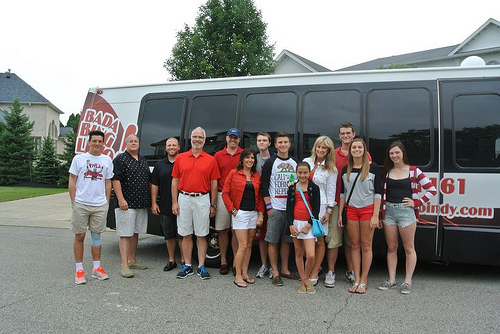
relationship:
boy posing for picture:
[67, 130, 115, 286] [1, 0, 494, 332]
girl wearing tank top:
[377, 139, 436, 294] [380, 167, 418, 202]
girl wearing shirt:
[337, 136, 385, 293] [337, 162, 386, 207]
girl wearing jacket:
[285, 161, 322, 291] [284, 178, 321, 225]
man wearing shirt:
[221, 124, 242, 171] [207, 150, 238, 177]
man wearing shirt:
[171, 126, 221, 280] [169, 144, 219, 194]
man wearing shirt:
[331, 114, 363, 186] [334, 142, 349, 169]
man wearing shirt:
[112, 132, 149, 279] [112, 154, 152, 208]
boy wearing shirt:
[67, 130, 115, 286] [68, 152, 113, 206]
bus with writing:
[67, 56, 499, 269] [433, 178, 488, 221]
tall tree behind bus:
[165, 0, 281, 75] [67, 56, 499, 269]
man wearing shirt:
[151, 137, 188, 273] [145, 159, 176, 211]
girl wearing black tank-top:
[377, 139, 436, 294] [385, 166, 414, 203]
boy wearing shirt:
[42, 107, 121, 286] [68, 152, 114, 207]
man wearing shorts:
[171, 126, 221, 280] [173, 185, 209, 235]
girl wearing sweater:
[285, 161, 322, 291] [283, 177, 320, 224]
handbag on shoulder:
[297, 182, 326, 238] [287, 182, 299, 195]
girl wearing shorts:
[222, 146, 265, 289] [231, 201, 278, 238]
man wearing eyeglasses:
[175, 124, 213, 294] [190, 134, 203, 142]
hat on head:
[226, 124, 250, 138] [216, 131, 245, 150]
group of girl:
[68, 128, 437, 298] [377, 139, 436, 294]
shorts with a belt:
[174, 189, 211, 236] [178, 187, 209, 196]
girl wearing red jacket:
[222, 146, 265, 289] [229, 172, 246, 197]